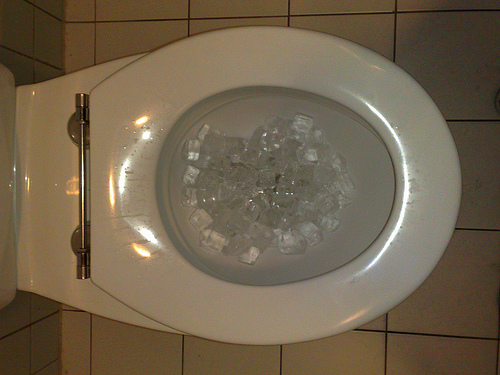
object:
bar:
[75, 94, 90, 281]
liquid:
[102, 112, 157, 232]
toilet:
[10, 25, 464, 347]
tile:
[387, 305, 495, 375]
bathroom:
[0, 0, 500, 375]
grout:
[382, 332, 390, 373]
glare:
[119, 214, 164, 259]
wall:
[12, 311, 62, 375]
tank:
[0, 64, 21, 310]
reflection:
[344, 89, 409, 279]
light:
[387, 223, 403, 249]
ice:
[180, 113, 359, 264]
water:
[121, 146, 140, 180]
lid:
[84, 24, 464, 346]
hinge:
[67, 92, 91, 280]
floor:
[61, 1, 500, 375]